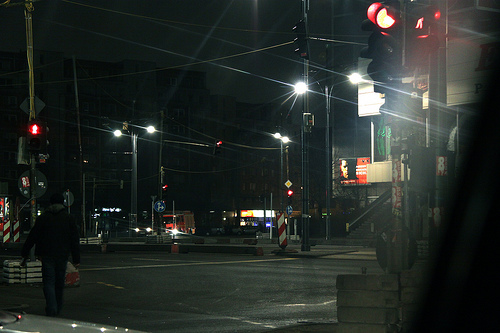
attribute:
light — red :
[357, 0, 448, 95]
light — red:
[364, 2, 437, 82]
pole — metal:
[298, 92, 312, 255]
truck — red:
[161, 213, 196, 236]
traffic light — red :
[353, 1, 432, 79]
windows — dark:
[18, 70, 235, 212]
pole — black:
[276, 64, 325, 263]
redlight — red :
[370, 0, 393, 34]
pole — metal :
[418, 0, 443, 333]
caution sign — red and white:
[273, 211, 290, 249]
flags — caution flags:
[272, 207, 291, 256]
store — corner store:
[209, 205, 288, 231]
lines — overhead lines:
[81, 109, 282, 161]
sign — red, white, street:
[277, 211, 288, 246]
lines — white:
[149, 249, 319, 279]